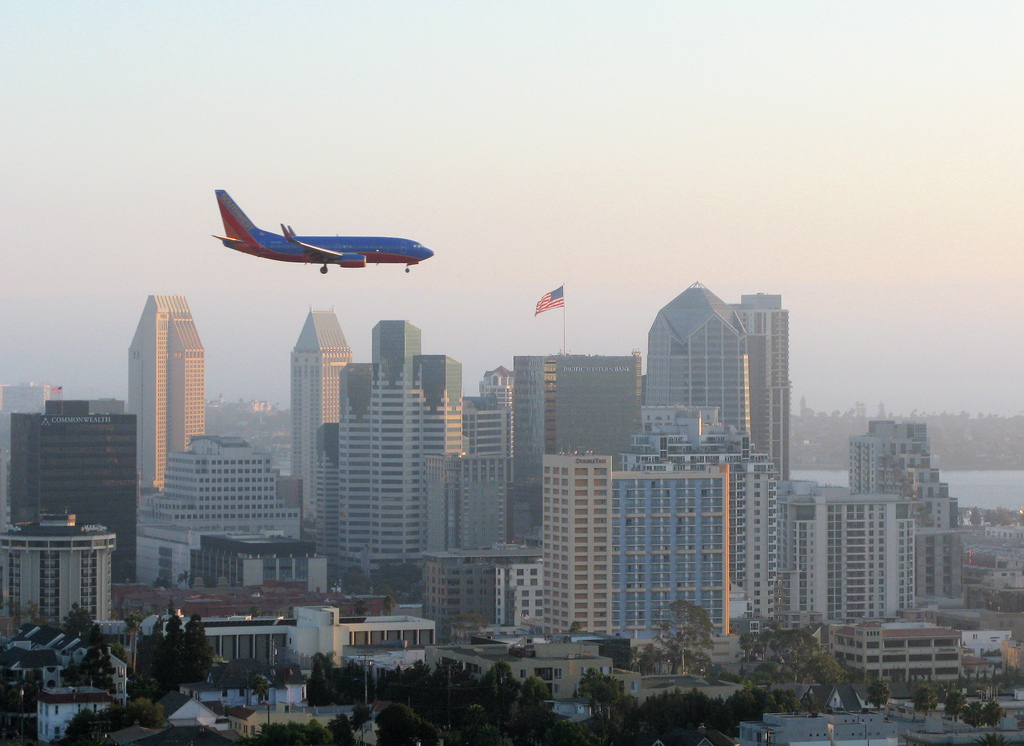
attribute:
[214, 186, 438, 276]
plane — blue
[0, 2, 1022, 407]
sky — white, hazy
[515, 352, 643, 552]
building — tall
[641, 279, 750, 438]
building — curved